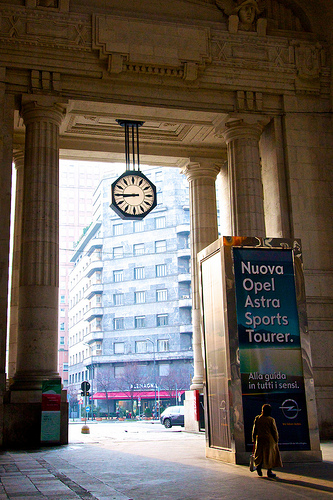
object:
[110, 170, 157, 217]
clock